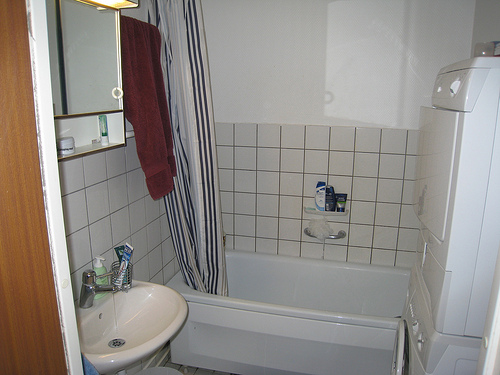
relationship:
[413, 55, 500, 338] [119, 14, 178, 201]
dryer across towel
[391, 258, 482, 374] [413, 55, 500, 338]
washing machine under dryer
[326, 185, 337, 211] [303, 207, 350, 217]
shampoo on shelf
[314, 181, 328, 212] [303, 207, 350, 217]
body wash on shelf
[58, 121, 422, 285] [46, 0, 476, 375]
tiles on walls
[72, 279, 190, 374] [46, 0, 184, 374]
sink against wall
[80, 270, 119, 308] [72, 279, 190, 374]
faucet on sink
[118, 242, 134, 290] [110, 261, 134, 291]
toothpaste in cup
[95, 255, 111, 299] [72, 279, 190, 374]
liquid soap on sink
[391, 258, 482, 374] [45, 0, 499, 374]
washing machine in bathroom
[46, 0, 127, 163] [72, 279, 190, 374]
medicine cabinet above sink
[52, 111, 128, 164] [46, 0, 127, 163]
shelf in medicine cabinet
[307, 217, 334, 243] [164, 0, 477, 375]
loofa in shower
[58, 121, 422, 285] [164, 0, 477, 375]
tiles in shower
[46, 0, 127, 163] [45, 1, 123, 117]
medicine cabinet has a mirror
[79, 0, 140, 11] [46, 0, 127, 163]
light above medicine cabinet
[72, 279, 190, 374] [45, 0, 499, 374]
sink in bathroom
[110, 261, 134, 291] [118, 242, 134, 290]
cup containing toothpaste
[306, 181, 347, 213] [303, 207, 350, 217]
soaps on shelf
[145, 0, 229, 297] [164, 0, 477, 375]
shower curtain in shower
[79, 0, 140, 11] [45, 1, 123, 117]
light above mirror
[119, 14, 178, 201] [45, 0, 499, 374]
towel in bathroom